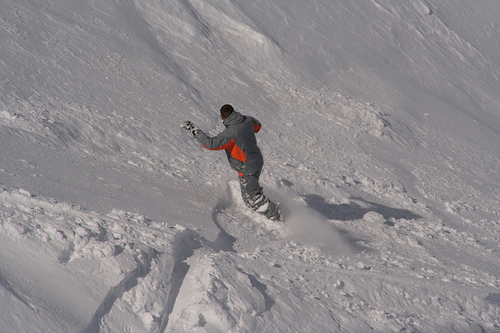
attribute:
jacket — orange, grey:
[196, 113, 265, 174]